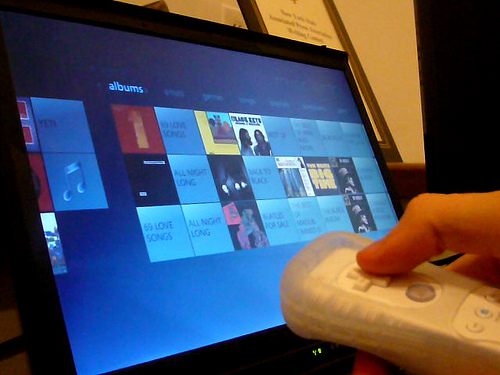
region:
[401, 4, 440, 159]
white edge along black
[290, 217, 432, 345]
thumb on remote button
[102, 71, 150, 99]
the word albums on blue background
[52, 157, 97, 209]
two music notes attached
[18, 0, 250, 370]
screen showing album covers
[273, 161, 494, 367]
hand holding a remote control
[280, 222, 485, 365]
a white remote control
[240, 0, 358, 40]
portion of document in a frame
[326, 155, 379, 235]
two images of same picture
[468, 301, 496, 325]
white button with blue dot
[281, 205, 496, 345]
This is a controller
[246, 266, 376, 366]
The controller is white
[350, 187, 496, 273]
This is a thumb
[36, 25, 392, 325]
This is a monitor screen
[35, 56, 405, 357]
This screen is on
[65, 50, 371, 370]
the monitor has lot of squares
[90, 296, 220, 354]
the background is blue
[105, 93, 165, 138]
the album is red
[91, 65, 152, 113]
this says "albums"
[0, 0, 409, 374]
An old Thinkpad running Windows 8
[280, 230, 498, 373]
A sleeved Wii Remote being used on the computer via Bluetooth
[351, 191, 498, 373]
The computer user's right hand holding a Wii Remote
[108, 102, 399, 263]
A thumbnail listing of albums on the computer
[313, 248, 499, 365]
A classic white Wii Remote inside a clear plastic sleeve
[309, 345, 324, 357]
The wireless and Bluetooth indicators lit up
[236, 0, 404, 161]
A framed certificate behind the computer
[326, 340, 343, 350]
Other indicators that are not lit up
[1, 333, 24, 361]
Part of a black cord behind the computer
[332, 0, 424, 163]
A white painted wall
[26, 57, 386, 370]
A black color television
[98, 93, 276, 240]
Monitor displaying something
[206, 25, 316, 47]
Black color panel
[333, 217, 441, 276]
Finger of the person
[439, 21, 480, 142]
Dark place near the television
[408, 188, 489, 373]
Hand with remote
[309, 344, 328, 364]
Green color light glowing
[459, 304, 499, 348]
Buttons of the remote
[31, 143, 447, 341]
Black color panel television with white color remote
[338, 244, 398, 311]
button on the remote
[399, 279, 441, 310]
round button on remote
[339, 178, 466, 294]
thumb on the remote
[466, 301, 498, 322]
blue button on remote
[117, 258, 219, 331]
blue screen on the television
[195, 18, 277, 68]
rim of the television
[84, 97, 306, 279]
icons on the television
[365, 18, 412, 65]
wall in the background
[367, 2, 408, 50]
white wall in background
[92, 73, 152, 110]
the word "albums"